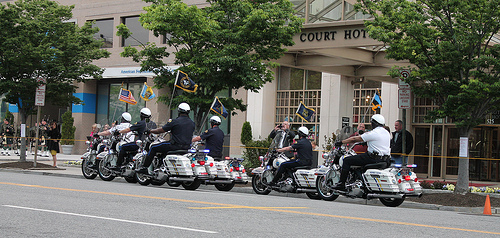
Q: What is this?
A: Bikers.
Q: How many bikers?
A: 6.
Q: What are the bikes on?
A: Pavement.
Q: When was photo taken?
A: Daytime.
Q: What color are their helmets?
A: White.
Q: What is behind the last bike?
A: Orange cone.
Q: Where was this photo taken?
A: On the street.